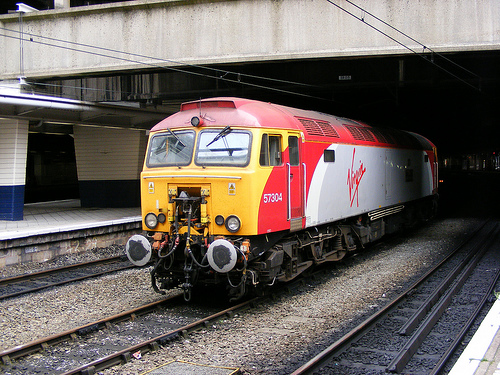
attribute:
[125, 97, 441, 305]
train — white, red, yellow, gray, colorful, engine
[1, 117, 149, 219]
supports — blue, white, wide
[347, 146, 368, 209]
name — red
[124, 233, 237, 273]
bumper — gray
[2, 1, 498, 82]
overpass — street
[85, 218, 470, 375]
gravel — gray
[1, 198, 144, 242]
walkway — tile, white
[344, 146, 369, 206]
logo — virgin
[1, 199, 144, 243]
platform — for people